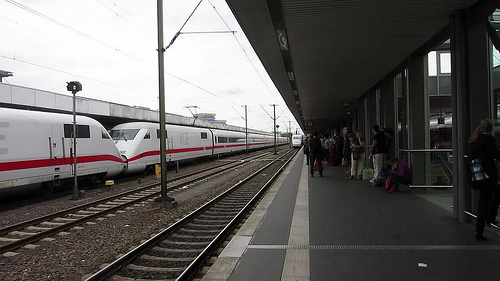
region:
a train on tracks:
[4, 51, 314, 231]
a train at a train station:
[14, 38, 327, 253]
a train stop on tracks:
[18, 34, 315, 197]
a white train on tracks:
[55, 47, 342, 279]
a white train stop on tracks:
[11, 45, 283, 220]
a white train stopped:
[14, 52, 369, 261]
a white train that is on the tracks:
[3, 38, 299, 202]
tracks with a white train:
[23, 50, 279, 230]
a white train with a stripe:
[10, 77, 327, 229]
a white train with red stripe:
[18, 59, 299, 209]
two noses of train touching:
[98, 151, 139, 173]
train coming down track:
[288, 134, 305, 147]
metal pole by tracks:
[155, 11, 170, 196]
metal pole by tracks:
[65, 82, 80, 197]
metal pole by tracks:
[270, 105, 278, 152]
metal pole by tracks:
[240, 105, 250, 154]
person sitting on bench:
[384, 160, 409, 191]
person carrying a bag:
[300, 134, 327, 174]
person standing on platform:
[464, 118, 497, 240]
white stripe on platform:
[282, 157, 304, 279]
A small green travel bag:
[361, 164, 373, 179]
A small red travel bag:
[385, 175, 393, 194]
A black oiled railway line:
[129, 206, 234, 269]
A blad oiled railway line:
[44, 187, 121, 227]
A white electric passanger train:
[113, 101, 281, 162]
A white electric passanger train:
[1, 99, 113, 199]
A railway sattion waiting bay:
[306, 126, 410, 203]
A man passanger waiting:
[364, 128, 381, 183]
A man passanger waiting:
[349, 127, 363, 178]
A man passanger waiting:
[298, 126, 325, 175]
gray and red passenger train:
[9, 112, 120, 178]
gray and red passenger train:
[52, 124, 126, 181]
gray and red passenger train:
[117, 130, 164, 172]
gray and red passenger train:
[160, 127, 213, 150]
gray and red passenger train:
[201, 130, 237, 152]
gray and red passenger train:
[228, 124, 280, 160]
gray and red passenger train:
[166, 122, 262, 161]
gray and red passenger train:
[11, 120, 245, 172]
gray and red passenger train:
[52, 105, 164, 173]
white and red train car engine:
[1, 104, 124, 201]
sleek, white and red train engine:
[107, 118, 214, 172]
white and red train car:
[210, 129, 247, 156]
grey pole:
[152, 2, 177, 209]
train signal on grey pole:
[64, 78, 89, 203]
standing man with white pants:
[369, 124, 389, 185]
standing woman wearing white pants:
[343, 127, 366, 181]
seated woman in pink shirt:
[383, 152, 413, 195]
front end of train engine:
[291, 131, 305, 146]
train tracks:
[89, 144, 305, 279]